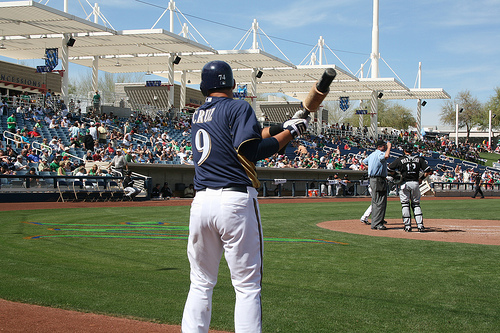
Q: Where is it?
A: This is at the field.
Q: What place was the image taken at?
A: It was taken at the field.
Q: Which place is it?
A: It is a field.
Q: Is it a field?
A: Yes, it is a field.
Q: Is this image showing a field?
A: Yes, it is showing a field.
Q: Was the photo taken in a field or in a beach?
A: It was taken at a field.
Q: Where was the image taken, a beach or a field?
A: It was taken at a field.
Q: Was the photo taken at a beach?
A: No, the picture was taken in a field.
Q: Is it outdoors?
A: Yes, it is outdoors.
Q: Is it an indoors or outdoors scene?
A: It is outdoors.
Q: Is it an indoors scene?
A: No, it is outdoors.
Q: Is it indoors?
A: No, it is outdoors.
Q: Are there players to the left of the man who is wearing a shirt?
A: Yes, there is a player to the left of the man.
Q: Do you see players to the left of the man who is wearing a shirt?
A: Yes, there is a player to the left of the man.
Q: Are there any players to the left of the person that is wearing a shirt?
A: Yes, there is a player to the left of the man.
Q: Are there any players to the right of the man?
A: No, the player is to the left of the man.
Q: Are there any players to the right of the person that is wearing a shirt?
A: No, the player is to the left of the man.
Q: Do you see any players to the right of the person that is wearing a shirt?
A: No, the player is to the left of the man.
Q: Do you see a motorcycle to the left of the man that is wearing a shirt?
A: No, there is a player to the left of the man.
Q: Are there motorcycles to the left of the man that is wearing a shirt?
A: No, there is a player to the left of the man.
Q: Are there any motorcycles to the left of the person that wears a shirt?
A: No, there is a player to the left of the man.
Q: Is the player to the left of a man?
A: Yes, the player is to the left of a man.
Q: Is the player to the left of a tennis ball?
A: No, the player is to the left of a man.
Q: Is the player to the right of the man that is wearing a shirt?
A: No, the player is to the left of the man.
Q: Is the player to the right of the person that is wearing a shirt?
A: No, the player is to the left of the man.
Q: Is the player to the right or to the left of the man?
A: The player is to the left of the man.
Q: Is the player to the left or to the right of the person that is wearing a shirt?
A: The player is to the left of the man.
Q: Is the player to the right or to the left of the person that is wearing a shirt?
A: The player is to the left of the man.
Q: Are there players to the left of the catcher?
A: Yes, there is a player to the left of the catcher.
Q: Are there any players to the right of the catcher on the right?
A: No, the player is to the left of the catcher.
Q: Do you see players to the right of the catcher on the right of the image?
A: No, the player is to the left of the catcher.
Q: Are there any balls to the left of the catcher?
A: No, there is a player to the left of the catcher.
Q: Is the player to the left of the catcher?
A: Yes, the player is to the left of the catcher.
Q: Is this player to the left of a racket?
A: No, the player is to the left of the catcher.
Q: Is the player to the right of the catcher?
A: No, the player is to the left of the catcher.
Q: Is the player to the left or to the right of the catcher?
A: The player is to the left of the catcher.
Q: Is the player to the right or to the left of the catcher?
A: The player is to the left of the catcher.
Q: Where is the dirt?
A: The dirt is on the field.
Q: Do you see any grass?
A: Yes, there is grass.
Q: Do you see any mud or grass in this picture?
A: Yes, there is grass.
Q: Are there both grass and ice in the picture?
A: No, there is grass but no ice.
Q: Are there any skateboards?
A: No, there are no skateboards.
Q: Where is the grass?
A: The grass is in the field.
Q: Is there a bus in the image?
A: No, there are no buses.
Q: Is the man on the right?
A: Yes, the man is on the right of the image.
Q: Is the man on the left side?
A: No, the man is on the right of the image.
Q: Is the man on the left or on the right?
A: The man is on the right of the image.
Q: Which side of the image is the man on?
A: The man is on the right of the image.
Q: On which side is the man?
A: The man is on the right of the image.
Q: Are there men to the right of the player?
A: Yes, there is a man to the right of the player.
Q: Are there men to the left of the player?
A: No, the man is to the right of the player.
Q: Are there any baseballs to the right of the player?
A: No, there is a man to the right of the player.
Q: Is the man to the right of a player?
A: Yes, the man is to the right of a player.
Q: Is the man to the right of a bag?
A: No, the man is to the right of a player.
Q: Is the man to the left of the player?
A: No, the man is to the right of the player.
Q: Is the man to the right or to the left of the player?
A: The man is to the right of the player.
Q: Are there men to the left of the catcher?
A: Yes, there is a man to the left of the catcher.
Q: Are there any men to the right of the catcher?
A: No, the man is to the left of the catcher.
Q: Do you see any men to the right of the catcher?
A: No, the man is to the left of the catcher.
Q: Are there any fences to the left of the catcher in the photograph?
A: No, there is a man to the left of the catcher.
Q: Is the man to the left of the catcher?
A: Yes, the man is to the left of the catcher.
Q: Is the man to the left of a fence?
A: No, the man is to the left of the catcher.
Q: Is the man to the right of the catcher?
A: No, the man is to the left of the catcher.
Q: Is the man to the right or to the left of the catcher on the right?
A: The man is to the left of the catcher.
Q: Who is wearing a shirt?
A: The man is wearing a shirt.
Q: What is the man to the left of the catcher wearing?
A: The man is wearing a shirt.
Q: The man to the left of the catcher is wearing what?
A: The man is wearing a shirt.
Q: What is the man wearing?
A: The man is wearing a shirt.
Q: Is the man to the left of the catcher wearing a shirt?
A: Yes, the man is wearing a shirt.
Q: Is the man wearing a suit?
A: No, the man is wearing a shirt.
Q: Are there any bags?
A: No, there are no bags.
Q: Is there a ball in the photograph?
A: No, there are no balls.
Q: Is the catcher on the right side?
A: Yes, the catcher is on the right of the image.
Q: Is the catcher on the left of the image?
A: No, the catcher is on the right of the image.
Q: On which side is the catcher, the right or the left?
A: The catcher is on the right of the image.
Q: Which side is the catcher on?
A: The catcher is on the right of the image.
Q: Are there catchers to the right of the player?
A: Yes, there is a catcher to the right of the player.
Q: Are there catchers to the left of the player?
A: No, the catcher is to the right of the player.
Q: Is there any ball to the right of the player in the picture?
A: No, there is a catcher to the right of the player.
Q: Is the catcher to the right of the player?
A: Yes, the catcher is to the right of the player.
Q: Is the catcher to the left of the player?
A: No, the catcher is to the right of the player.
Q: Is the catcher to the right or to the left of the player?
A: The catcher is to the right of the player.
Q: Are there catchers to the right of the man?
A: Yes, there is a catcher to the right of the man.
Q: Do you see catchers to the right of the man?
A: Yes, there is a catcher to the right of the man.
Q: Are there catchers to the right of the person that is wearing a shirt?
A: Yes, there is a catcher to the right of the man.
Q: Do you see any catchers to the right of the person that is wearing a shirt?
A: Yes, there is a catcher to the right of the man.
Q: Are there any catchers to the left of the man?
A: No, the catcher is to the right of the man.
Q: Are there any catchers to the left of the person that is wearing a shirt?
A: No, the catcher is to the right of the man.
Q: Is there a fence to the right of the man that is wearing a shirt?
A: No, there is a catcher to the right of the man.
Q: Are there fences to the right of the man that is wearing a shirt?
A: No, there is a catcher to the right of the man.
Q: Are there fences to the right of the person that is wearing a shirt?
A: No, there is a catcher to the right of the man.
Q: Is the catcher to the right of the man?
A: Yes, the catcher is to the right of the man.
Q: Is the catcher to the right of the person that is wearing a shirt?
A: Yes, the catcher is to the right of the man.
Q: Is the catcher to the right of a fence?
A: No, the catcher is to the right of the man.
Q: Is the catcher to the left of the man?
A: No, the catcher is to the right of the man.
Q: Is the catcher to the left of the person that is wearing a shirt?
A: No, the catcher is to the right of the man.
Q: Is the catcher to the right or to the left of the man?
A: The catcher is to the right of the man.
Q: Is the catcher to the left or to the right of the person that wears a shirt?
A: The catcher is to the right of the man.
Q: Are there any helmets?
A: Yes, there is a helmet.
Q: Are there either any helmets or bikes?
A: Yes, there is a helmet.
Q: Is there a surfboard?
A: No, there are no surfboards.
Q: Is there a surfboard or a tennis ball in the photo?
A: No, there are no surfboards or tennis balls.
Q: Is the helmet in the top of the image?
A: Yes, the helmet is in the top of the image.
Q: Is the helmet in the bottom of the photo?
A: No, the helmet is in the top of the image.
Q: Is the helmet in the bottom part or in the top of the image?
A: The helmet is in the top of the image.